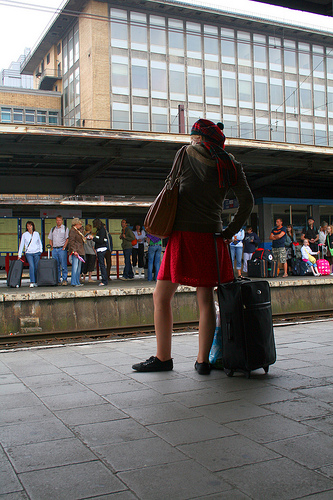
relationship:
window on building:
[109, 6, 128, 48] [1, 1, 331, 147]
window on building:
[129, 56, 150, 98] [1, 1, 331, 147]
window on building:
[187, 66, 203, 103] [1, 1, 331, 147]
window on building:
[220, 25, 236, 65] [1, 1, 331, 147]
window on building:
[284, 80, 299, 114] [1, 1, 331, 147]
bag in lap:
[306, 254, 316, 264] [302, 254, 317, 262]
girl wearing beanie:
[300, 239, 322, 278] [189, 118, 238, 187]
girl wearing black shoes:
[300, 239, 322, 278] [128, 356, 176, 368]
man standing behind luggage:
[37, 208, 80, 260] [23, 240, 62, 294]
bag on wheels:
[212, 232, 277, 379] [224, 360, 272, 377]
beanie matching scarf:
[189, 118, 238, 187] [196, 141, 238, 189]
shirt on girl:
[143, 227, 166, 249] [300, 239, 322, 278]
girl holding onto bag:
[300, 239, 322, 278] [212, 232, 277, 379]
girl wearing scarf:
[300, 239, 322, 278] [196, 136, 240, 195]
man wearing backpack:
[118, 217, 139, 283] [129, 226, 137, 246]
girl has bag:
[300, 239, 322, 278] [212, 232, 277, 379]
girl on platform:
[300, 239, 322, 278] [0, 315, 332, 498]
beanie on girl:
[189, 118, 238, 187] [300, 239, 322, 278]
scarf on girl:
[205, 138, 238, 189] [300, 239, 322, 278]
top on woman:
[158, 141, 258, 240] [160, 115, 244, 252]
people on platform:
[9, 215, 332, 277] [0, 274, 332, 338]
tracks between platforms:
[1, 308, 332, 352] [3, 107, 328, 475]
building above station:
[33, 4, 325, 141] [2, 177, 326, 303]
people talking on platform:
[60, 207, 110, 288] [0, 274, 333, 338]